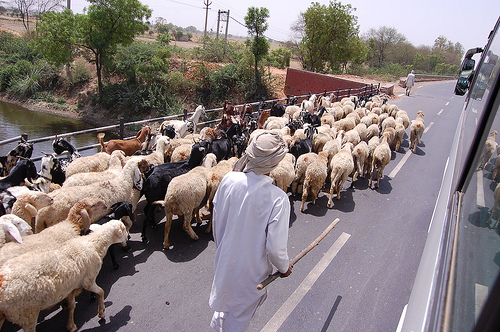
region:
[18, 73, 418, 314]
the sheep on the side of the road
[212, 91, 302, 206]
a man wearing a turban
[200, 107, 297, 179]
the turban is beige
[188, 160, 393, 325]
a man is carrying a stick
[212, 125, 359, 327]
the man is walking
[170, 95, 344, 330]
a man beside the sheep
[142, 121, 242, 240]
the goat is black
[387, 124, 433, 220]
the line is painted on the ground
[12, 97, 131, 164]
the water is calm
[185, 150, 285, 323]
the dress is white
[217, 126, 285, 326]
a man wearing a beige turban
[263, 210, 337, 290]
a brown stick in a man's hand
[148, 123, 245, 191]
two black goats in the middle of a group of goats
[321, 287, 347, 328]
the shadow of a stick on the ground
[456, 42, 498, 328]
the windows on the side of a bus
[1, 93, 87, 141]
a river below a bridge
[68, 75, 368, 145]
a metal guard rail along a bridge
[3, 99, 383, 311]
a group of goats being guided across a bridge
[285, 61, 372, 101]
a red brick wall by the bridge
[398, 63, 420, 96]
a man walking down the road in front of the goats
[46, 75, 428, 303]
person walking with animals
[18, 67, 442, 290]
person walking with plenty animals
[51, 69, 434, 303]
person walking with several animals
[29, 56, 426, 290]
person walking with group of animals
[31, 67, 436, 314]
person walking with lots of animals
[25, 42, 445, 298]
person walking with animals down road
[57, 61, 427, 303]
person walking with animals down street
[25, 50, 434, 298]
male person walking with animals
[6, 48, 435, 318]
tall person walking with animals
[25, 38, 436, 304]
man walking with animals down street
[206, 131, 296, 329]
Shepherd guiding sheep down road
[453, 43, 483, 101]
Side view mirror of passing vehicle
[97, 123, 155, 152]
Brown goat walking with sheep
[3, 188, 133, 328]
Light colored sheep walking on road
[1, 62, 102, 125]
River underneath road bridge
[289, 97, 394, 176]
Herd of sheep and goats walking in road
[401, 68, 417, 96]
Person walking on the side of the road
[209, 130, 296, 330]
Man in white clothing and turban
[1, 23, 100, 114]
Trees and bushes next to river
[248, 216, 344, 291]
Staff carried by shepherd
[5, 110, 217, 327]
flock of sheep on road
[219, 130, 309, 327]
man herding sheep down road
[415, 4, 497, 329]
large bus on highway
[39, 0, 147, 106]
green tree on riverbank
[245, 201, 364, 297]
the shepherds walking stick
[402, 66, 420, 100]
a man in the distance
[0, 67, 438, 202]
bridge over river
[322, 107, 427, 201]
all white sheep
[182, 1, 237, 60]
utility pole on riverbank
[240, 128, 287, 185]
man's beige turban